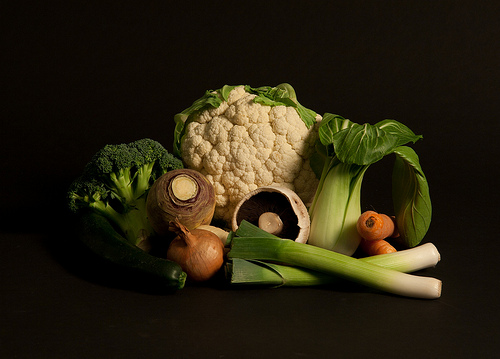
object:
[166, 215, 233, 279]
vegetable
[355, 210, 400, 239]
vegetable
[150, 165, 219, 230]
vegetable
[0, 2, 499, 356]
black background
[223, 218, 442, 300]
celery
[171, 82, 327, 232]
cauliflower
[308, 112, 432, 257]
veggie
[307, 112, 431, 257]
long leaves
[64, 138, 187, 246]
broccoli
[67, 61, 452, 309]
vegetable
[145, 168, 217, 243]
rutabaga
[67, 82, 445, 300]
vegetables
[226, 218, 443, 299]
two leeks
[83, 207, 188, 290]
zucchini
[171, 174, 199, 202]
root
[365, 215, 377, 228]
root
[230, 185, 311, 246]
mushroom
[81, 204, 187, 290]
cucumber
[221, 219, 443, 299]
vegetables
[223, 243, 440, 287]
vegetables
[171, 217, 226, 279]
onion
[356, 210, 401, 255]
carrots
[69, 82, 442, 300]
greenery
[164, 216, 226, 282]
onion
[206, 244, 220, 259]
light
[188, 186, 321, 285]
root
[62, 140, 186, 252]
vegetable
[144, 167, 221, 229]
vegetable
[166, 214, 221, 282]
vegetable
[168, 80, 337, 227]
vegetable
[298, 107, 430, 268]
vegetable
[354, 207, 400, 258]
vegetable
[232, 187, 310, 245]
vegetable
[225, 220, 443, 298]
vegetable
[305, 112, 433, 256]
greens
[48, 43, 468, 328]
picture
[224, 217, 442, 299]
leek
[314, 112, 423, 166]
leaves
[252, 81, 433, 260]
vegetable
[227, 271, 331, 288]
edge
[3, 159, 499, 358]
table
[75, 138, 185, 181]
top